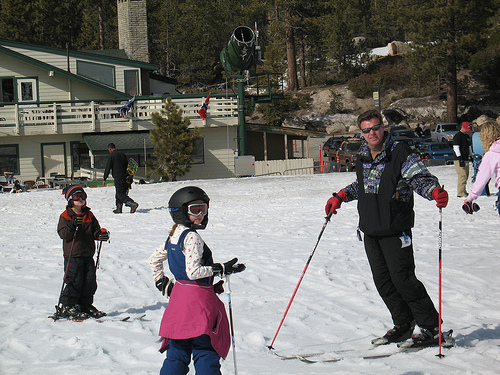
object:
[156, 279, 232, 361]
jacket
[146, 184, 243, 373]
girl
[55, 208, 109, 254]
jacket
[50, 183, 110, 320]
child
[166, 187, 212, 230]
helmet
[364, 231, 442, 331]
pants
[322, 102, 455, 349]
man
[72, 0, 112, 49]
tree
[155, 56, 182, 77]
branches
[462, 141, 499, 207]
sweater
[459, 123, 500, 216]
woman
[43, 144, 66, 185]
door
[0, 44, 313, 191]
house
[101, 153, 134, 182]
shirt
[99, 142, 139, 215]
man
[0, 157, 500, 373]
snow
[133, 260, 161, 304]
tracks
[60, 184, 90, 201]
hat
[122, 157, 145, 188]
snowboard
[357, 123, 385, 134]
sunglasses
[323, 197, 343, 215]
glove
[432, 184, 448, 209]
glove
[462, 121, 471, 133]
cap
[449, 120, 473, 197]
man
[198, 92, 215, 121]
flag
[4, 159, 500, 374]
ground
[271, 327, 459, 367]
skis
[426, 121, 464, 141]
cars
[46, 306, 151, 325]
skis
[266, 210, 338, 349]
ski pole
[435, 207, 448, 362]
ski pole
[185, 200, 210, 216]
goggles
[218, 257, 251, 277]
glove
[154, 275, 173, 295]
glove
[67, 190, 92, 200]
goggles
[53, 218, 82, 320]
ski pole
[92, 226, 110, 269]
ski pole